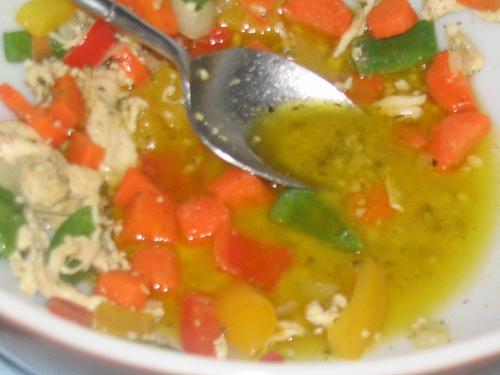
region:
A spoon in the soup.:
[180, 25, 363, 210]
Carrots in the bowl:
[105, 179, 178, 255]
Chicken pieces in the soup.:
[63, 93, 142, 163]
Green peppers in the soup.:
[351, 34, 444, 69]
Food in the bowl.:
[76, 92, 465, 350]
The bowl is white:
[51, 289, 472, 374]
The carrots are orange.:
[135, 187, 222, 255]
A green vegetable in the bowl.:
[346, 28, 465, 80]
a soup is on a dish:
[1, 1, 496, 373]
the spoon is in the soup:
[66, 1, 404, 199]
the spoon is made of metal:
[71, 0, 392, 195]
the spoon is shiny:
[71, 0, 392, 197]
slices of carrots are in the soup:
[96, 157, 258, 300]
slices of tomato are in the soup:
[144, 146, 206, 202]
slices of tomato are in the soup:
[215, 222, 296, 283]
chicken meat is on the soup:
[85, 100, 135, 175]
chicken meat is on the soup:
[22, 160, 99, 210]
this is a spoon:
[43, 0, 380, 207]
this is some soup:
[25, 16, 475, 352]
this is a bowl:
[13, 0, 493, 374]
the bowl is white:
[5, 10, 485, 371]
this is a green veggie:
[258, 162, 357, 256]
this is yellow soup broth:
[283, 114, 456, 287]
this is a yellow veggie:
[205, 260, 396, 360]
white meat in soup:
[16, 67, 118, 298]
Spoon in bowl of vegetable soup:
[65, 10, 406, 203]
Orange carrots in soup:
[112, 159, 289, 289]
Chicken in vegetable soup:
[2, 104, 102, 289]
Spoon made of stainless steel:
[77, 0, 411, 199]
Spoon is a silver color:
[91, 5, 394, 202]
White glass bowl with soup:
[15, 223, 486, 369]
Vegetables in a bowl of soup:
[13, 52, 490, 364]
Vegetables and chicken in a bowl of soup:
[19, 127, 481, 370]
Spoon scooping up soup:
[123, 10, 404, 201]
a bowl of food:
[3, 1, 494, 349]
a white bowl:
[6, 258, 451, 373]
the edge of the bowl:
[25, 300, 157, 351]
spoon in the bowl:
[91, 4, 393, 183]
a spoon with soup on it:
[92, 22, 403, 192]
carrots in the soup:
[117, 167, 234, 239]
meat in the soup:
[11, 134, 86, 199]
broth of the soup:
[325, 133, 420, 203]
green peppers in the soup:
[356, 39, 424, 57]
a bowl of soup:
[3, 3, 490, 372]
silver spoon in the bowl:
[121, 30, 384, 207]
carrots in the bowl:
[118, 171, 225, 253]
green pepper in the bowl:
[271, 178, 356, 268]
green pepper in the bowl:
[344, 23, 447, 73]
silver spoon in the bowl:
[77, 5, 401, 192]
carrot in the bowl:
[112, 167, 269, 241]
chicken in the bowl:
[18, 96, 134, 208]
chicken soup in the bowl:
[6, 4, 488, 324]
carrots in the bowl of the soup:
[111, 170, 284, 295]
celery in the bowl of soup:
[339, 14, 441, 75]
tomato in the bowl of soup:
[212, 223, 293, 290]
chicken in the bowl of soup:
[16, 135, 88, 214]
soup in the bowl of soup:
[106, 8, 404, 215]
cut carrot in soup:
[209, 228, 290, 284]